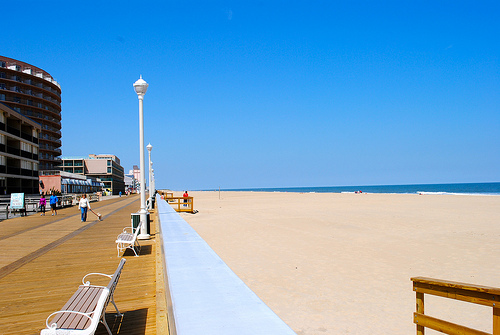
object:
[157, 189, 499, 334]
sand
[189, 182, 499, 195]
ocean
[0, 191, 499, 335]
ground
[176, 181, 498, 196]
water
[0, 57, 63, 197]
hotel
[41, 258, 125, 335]
bench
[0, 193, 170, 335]
deck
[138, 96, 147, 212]
post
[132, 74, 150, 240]
lightpost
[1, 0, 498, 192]
blue sky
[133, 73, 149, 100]
poll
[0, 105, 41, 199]
building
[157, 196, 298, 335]
board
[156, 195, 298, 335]
wall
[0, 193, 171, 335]
boardwalk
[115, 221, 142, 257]
bench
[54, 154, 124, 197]
hotel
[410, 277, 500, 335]
handrail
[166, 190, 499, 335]
beach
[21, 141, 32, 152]
window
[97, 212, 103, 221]
dog